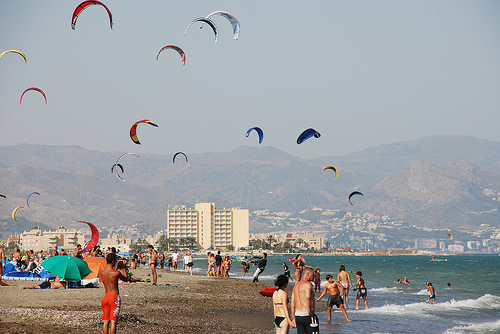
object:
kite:
[242, 123, 266, 149]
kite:
[294, 126, 323, 147]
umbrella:
[38, 252, 94, 285]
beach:
[0, 247, 342, 333]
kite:
[320, 162, 340, 181]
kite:
[126, 116, 162, 147]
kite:
[69, 0, 117, 33]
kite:
[17, 85, 51, 109]